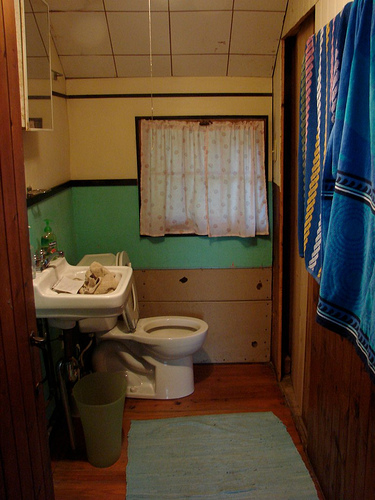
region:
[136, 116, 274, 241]
curtain on the window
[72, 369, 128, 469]
trash can on floor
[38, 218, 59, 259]
hand soap on sink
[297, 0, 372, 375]
two towels on the door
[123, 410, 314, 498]
rug on the floor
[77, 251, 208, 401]
white toilet next to the window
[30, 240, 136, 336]
white sink on wall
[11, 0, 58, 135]
medicine cabinet on wall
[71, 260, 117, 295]
towel on sink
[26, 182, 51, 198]
soap holder on wall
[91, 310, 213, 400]
white porcelain toilet bowl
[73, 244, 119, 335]
white porcelain toilet tank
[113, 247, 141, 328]
toilet lid in UP position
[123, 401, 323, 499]
light blue area rug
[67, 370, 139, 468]
green plastic trash can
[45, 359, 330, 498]
knotty wooden floor boards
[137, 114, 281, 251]
flower pattern window curtain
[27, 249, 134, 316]
white porcelain bathroom sink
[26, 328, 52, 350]
black metal door handle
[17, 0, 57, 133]
bathroom mirror high on wall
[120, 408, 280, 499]
blue rug on the floor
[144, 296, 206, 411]
white toilet bowl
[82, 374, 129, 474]
plastic garbage can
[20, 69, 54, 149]
medicine cabinet with mirror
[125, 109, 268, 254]
a curtain covering a window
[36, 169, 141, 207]
wood trim on the wall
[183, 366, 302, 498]
hardwood floors with a rug covering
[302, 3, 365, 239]
multicolored towel hanging on wall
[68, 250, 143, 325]
a towel in a bathroom sink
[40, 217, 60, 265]
a plastic soap bottle with a green lid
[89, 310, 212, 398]
White commode inside bathroom.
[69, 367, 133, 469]
Plastic trash can next to bathroom sink.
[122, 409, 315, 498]
Blue gray rug on bathroom floor.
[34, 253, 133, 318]
White sink in bathroom.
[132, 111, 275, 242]
White curtain with pink designs over window.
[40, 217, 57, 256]
Liquid hand soap sitting on sink.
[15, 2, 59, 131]
Medicine cabinet with mirror over sink.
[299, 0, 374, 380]
Blue bath towel spread over door.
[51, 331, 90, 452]
Plumbing under bathroom sink.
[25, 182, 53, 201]
Soap dish mounted on wall over sink.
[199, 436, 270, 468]
rug on the floor.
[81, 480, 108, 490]
floor board made of wood.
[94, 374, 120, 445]
trash can under the sink.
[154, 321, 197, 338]
bowl of the toilet.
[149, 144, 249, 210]
curtain on the window.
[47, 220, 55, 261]
soap on the sink.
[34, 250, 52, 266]
faucet on the sink.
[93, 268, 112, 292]
towel in the sink.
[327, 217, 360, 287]
towel on the shower.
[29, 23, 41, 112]
mirror on the wall.